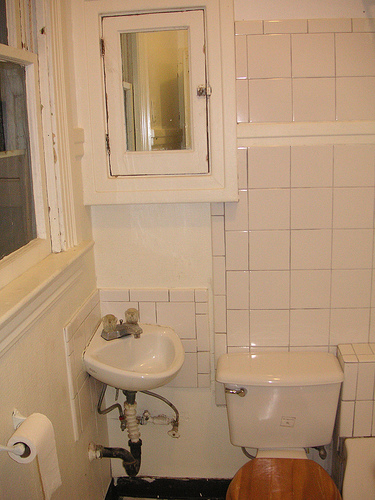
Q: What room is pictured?
A: It is a bathroom.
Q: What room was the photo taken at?
A: It was taken at the bathroom.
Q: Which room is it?
A: It is a bathroom.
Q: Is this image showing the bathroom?
A: Yes, it is showing the bathroom.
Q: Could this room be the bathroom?
A: Yes, it is the bathroom.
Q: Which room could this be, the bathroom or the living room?
A: It is the bathroom.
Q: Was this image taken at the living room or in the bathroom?
A: It was taken at the bathroom.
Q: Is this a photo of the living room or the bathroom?
A: It is showing the bathroom.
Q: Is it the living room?
A: No, it is the bathroom.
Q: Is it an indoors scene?
A: Yes, it is indoors.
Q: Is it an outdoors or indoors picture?
A: It is indoors.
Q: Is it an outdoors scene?
A: No, it is indoors.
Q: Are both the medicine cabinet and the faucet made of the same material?
A: No, the medicine cabinet is made of wood and the faucet is made of metal.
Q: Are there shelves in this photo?
A: No, there are no shelves.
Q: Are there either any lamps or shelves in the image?
A: No, there are no shelves or lamps.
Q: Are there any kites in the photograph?
A: No, there are no kites.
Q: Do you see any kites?
A: No, there are no kites.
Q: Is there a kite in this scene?
A: No, there are no kites.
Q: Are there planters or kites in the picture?
A: No, there are no kites or planters.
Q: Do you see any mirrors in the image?
A: Yes, there is a mirror.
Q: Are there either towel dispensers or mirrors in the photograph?
A: Yes, there is a mirror.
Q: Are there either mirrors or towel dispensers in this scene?
A: Yes, there is a mirror.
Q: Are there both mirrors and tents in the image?
A: No, there is a mirror but no tents.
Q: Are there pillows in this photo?
A: No, there are no pillows.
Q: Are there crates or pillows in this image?
A: No, there are no pillows or crates.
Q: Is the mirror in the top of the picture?
A: Yes, the mirror is in the top of the image.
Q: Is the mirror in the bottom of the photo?
A: No, the mirror is in the top of the image.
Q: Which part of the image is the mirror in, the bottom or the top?
A: The mirror is in the top of the image.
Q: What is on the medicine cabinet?
A: The mirror is on the medicine cabinet.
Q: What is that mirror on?
A: The mirror is on the medicine cabinet.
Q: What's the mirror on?
A: The mirror is on the medicine cabinet.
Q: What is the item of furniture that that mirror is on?
A: The piece of furniture is a medicine cabinet.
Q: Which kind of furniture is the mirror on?
A: The mirror is on the medicine cabinet.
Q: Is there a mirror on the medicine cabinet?
A: Yes, there is a mirror on the medicine cabinet.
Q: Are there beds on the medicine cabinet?
A: No, there is a mirror on the medicine cabinet.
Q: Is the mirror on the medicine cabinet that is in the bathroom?
A: Yes, the mirror is on the medicine cabinet.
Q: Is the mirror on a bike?
A: No, the mirror is on the medicine cabinet.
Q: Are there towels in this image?
A: No, there are no towels.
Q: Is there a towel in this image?
A: No, there are no towels.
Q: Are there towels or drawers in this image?
A: No, there are no towels or drawers.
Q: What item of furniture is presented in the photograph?
A: The piece of furniture is a medicine cabinet.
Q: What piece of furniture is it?
A: The piece of furniture is a medicine cabinet.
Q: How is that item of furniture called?
A: This is a medicine cabinet.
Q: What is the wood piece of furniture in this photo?
A: The piece of furniture is a medicine cabinet.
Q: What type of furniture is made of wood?
A: The furniture is a medicine cabinet.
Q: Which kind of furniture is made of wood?
A: The furniture is a medicine cabinet.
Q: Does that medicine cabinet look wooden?
A: Yes, the medicine cabinet is wooden.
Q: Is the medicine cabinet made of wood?
A: Yes, the medicine cabinet is made of wood.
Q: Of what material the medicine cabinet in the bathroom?
A: The medicine cabinet is made of wood.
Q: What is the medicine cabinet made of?
A: The medicine cabinet is made of wood.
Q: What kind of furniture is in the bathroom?
A: The piece of furniture is a medicine cabinet.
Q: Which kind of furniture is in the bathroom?
A: The piece of furniture is a medicine cabinet.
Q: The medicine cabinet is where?
A: The medicine cabinet is in the bathroom.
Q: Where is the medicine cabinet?
A: The medicine cabinet is in the bathroom.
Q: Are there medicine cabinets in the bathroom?
A: Yes, there is a medicine cabinet in the bathroom.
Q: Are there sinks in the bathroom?
A: No, there is a medicine cabinet in the bathroom.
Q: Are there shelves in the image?
A: No, there are no shelves.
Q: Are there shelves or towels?
A: No, there are no shelves or towels.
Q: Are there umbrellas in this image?
A: No, there are no umbrellas.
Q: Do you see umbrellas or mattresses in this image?
A: No, there are no umbrellas or mattresses.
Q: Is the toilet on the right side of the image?
A: Yes, the toilet is on the right of the image.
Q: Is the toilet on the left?
A: No, the toilet is on the right of the image.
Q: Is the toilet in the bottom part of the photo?
A: Yes, the toilet is in the bottom of the image.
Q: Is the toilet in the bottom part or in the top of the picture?
A: The toilet is in the bottom of the image.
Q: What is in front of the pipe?
A: The toilet is in front of the pipe.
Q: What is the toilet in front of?
A: The toilet is in front of the pipe.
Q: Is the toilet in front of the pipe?
A: Yes, the toilet is in front of the pipe.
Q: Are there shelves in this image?
A: No, there are no shelves.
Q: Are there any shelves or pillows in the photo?
A: No, there are no shelves or pillows.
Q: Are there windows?
A: Yes, there is a window.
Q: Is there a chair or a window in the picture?
A: Yes, there is a window.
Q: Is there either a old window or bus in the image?
A: Yes, there is an old window.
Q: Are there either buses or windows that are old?
A: Yes, the window is old.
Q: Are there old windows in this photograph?
A: Yes, there is an old window.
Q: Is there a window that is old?
A: Yes, there is a window that is old.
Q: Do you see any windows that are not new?
A: Yes, there is a old window.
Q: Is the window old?
A: Yes, the window is old.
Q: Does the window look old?
A: Yes, the window is old.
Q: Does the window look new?
A: No, the window is old.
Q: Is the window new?
A: No, the window is old.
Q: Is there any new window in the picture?
A: No, there is a window but it is old.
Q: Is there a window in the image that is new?
A: No, there is a window but it is old.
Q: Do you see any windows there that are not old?
A: No, there is a window but it is old.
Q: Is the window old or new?
A: The window is old.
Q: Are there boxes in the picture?
A: No, there are no boxes.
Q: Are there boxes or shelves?
A: No, there are no boxes or shelves.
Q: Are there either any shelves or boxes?
A: No, there are no boxes or shelves.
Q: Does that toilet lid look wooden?
A: Yes, the toilet lid is wooden.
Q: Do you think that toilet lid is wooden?
A: Yes, the toilet lid is wooden.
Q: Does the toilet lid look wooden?
A: Yes, the toilet lid is wooden.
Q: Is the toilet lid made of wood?
A: Yes, the toilet lid is made of wood.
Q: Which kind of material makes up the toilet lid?
A: The toilet lid is made of wood.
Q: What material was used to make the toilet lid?
A: The toilet lid is made of wood.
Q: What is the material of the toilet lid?
A: The toilet lid is made of wood.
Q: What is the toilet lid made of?
A: The toilet lid is made of wood.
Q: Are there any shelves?
A: No, there are no shelves.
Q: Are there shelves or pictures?
A: No, there are no shelves or pictures.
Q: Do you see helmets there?
A: No, there are no helmets.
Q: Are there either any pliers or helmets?
A: No, there are no helmets or pliers.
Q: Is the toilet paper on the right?
A: No, the toilet paper is on the left of the image.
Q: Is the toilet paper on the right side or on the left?
A: The toilet paper is on the left of the image.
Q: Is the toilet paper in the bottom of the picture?
A: Yes, the toilet paper is in the bottom of the image.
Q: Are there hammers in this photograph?
A: No, there are no hammers.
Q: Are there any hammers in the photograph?
A: No, there are no hammers.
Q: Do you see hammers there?
A: No, there are no hammers.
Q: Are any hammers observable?
A: No, there are no hammers.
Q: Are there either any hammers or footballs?
A: No, there are no hammers or footballs.